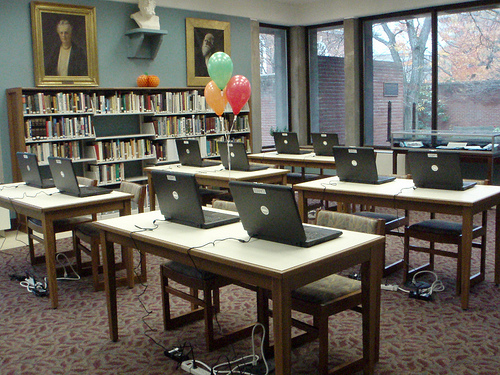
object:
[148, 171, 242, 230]
laptop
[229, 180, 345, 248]
laptop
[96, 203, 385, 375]
desk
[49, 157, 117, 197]
laptop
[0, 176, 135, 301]
desk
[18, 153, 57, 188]
laptop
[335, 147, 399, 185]
laptop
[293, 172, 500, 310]
desk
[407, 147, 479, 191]
laptop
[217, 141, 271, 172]
laptop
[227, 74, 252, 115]
balloon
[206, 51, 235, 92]
balloon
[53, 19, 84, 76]
man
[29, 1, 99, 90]
portrait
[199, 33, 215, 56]
woman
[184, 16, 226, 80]
portrait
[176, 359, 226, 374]
outlet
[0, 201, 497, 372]
floor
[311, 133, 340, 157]
laptop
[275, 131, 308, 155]
laptops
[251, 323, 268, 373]
cord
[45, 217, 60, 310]
leg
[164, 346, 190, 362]
port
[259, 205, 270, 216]
logo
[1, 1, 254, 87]
wall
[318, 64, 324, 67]
bricks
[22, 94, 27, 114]
books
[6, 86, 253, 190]
shelf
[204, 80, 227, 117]
balloon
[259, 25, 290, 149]
window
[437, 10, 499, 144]
window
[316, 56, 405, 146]
wall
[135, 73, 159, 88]
decoration